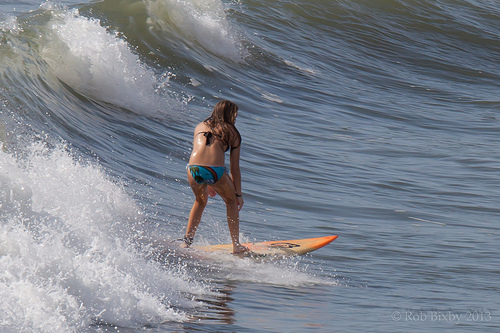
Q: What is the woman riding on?
A: A surfboard.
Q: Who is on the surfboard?
A: A woman.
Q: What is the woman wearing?
A: A colorful bikini.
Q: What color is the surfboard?
A: Orange.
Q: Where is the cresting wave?
A: Behind the surfer.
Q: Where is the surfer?
A: In the ocean.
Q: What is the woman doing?
A: Surfing in the ocean.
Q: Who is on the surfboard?
A: Woman in bikini.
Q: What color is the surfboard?
A: Orange.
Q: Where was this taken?
A: Ocean.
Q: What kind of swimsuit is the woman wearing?
A: Bikini.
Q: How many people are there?
A: 1.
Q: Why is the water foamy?
A: Waves.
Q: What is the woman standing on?
A: Surfboard.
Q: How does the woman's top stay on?
A: Ties in back.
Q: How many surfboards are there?
A: 1.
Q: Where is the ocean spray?
A: Behind the surfer.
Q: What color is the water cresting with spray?
A: Green.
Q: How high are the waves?
A: Higher than the surfer.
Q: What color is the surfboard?
A: Yellow-orange.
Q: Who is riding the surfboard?
A: A woman.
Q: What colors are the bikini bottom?
A: Blue and black.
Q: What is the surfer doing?
A: Riding a wave.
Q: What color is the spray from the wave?
A: White.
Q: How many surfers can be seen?
A: One.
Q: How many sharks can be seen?
A: None.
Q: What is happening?
A: She is surfing.